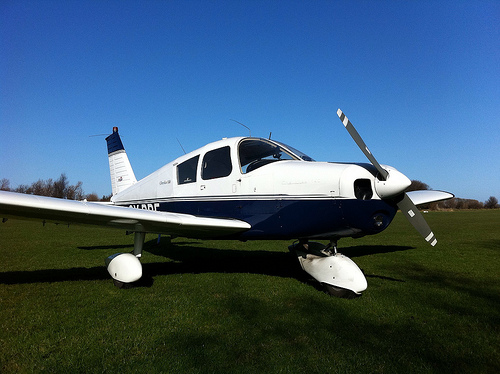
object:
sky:
[2, 1, 500, 202]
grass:
[0, 207, 500, 373]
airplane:
[0, 109, 455, 296]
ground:
[0, 205, 500, 373]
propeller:
[334, 107, 443, 254]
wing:
[0, 187, 252, 230]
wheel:
[112, 279, 140, 293]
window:
[202, 148, 233, 179]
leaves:
[45, 181, 69, 190]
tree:
[484, 191, 498, 211]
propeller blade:
[333, 106, 390, 178]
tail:
[98, 124, 141, 195]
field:
[0, 206, 500, 372]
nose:
[397, 170, 414, 192]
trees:
[2, 171, 96, 201]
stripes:
[112, 191, 347, 201]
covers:
[108, 251, 142, 281]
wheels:
[321, 282, 354, 298]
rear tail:
[105, 158, 130, 180]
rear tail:
[107, 134, 122, 155]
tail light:
[106, 125, 125, 135]